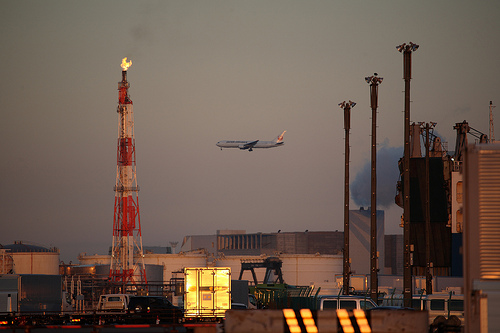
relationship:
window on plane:
[230, 140, 232, 147] [215, 127, 295, 153]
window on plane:
[217, 142, 219, 144] [215, 127, 295, 153]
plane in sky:
[216, 130, 288, 152] [1, 1, 497, 264]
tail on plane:
[275, 125, 287, 142] [215, 130, 284, 150]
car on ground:
[127, 297, 188, 323] [10, 299, 494, 331]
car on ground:
[127, 295, 183, 317] [10, 299, 494, 331]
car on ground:
[320, 289, 377, 306] [10, 299, 494, 331]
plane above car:
[211, 124, 291, 159] [127, 295, 183, 317]